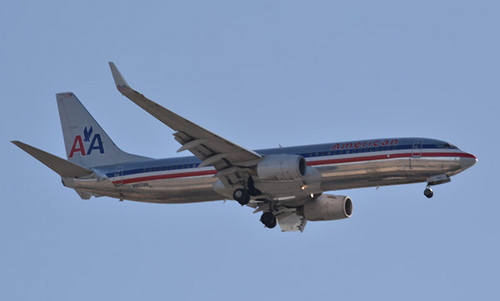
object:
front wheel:
[424, 188, 433, 197]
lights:
[310, 193, 314, 199]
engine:
[256, 154, 307, 183]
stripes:
[304, 153, 476, 166]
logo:
[69, 125, 106, 159]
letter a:
[68, 135, 85, 158]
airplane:
[9, 61, 478, 233]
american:
[331, 139, 398, 150]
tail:
[54, 91, 156, 168]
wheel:
[260, 212, 276, 226]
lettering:
[68, 133, 105, 157]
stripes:
[303, 148, 470, 162]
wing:
[106, 61, 264, 172]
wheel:
[233, 189, 246, 201]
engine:
[303, 194, 353, 221]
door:
[411, 138, 425, 157]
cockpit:
[443, 142, 459, 149]